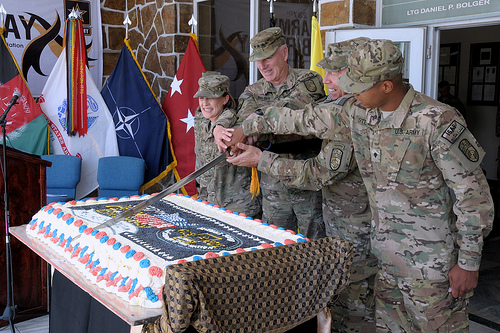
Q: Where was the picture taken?
A: A party.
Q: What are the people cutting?
A: A cake.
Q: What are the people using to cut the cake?
A: A knife.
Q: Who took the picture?
A: A person.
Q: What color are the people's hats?
A: Camouflage.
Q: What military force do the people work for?
A: U.S. Army.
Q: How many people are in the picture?
A: 4.